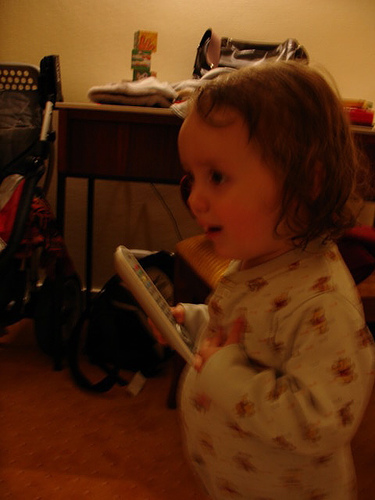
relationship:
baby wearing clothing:
[147, 59, 375, 500] [177, 230, 374, 500]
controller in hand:
[112, 243, 198, 367] [188, 320, 235, 363]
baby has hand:
[147, 59, 375, 500] [188, 320, 235, 363]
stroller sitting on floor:
[0, 48, 85, 357] [0, 317, 373, 498]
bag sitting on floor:
[68, 249, 190, 409] [3, 363, 197, 499]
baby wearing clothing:
[147, 59, 375, 500] [205, 286, 356, 466]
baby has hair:
[147, 59, 375, 500] [191, 60, 360, 250]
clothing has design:
[177, 230, 374, 500] [308, 276, 331, 298]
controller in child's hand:
[112, 243, 198, 367] [155, 71, 374, 497]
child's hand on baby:
[191, 311, 247, 375] [147, 59, 375, 500]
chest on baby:
[181, 284, 284, 456] [147, 59, 375, 500]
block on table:
[133, 66, 151, 82] [53, 86, 233, 232]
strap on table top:
[193, 30, 212, 83] [52, 94, 374, 136]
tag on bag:
[123, 367, 148, 399] [81, 246, 178, 384]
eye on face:
[202, 166, 229, 189] [177, 112, 264, 255]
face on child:
[177, 112, 264, 255] [374, 57, 375, 493]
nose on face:
[188, 169, 210, 218] [177, 112, 264, 255]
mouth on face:
[198, 222, 218, 239] [176, 83, 282, 262]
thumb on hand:
[226, 314, 246, 342] [193, 319, 243, 369]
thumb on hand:
[163, 299, 187, 324] [144, 296, 191, 343]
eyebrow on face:
[193, 155, 225, 166] [156, 85, 303, 256]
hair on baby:
[191, 60, 360, 250] [144, 60, 373, 498]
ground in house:
[63, 427, 113, 472] [61, 8, 309, 65]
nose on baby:
[185, 189, 209, 214] [144, 60, 373, 498]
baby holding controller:
[147, 59, 375, 500] [113, 243, 199, 364]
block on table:
[131, 28, 159, 53] [50, 100, 374, 293]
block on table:
[131, 49, 152, 68] [50, 100, 374, 293]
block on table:
[131, 66, 157, 81] [50, 100, 374, 293]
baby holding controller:
[147, 59, 375, 500] [95, 229, 205, 372]